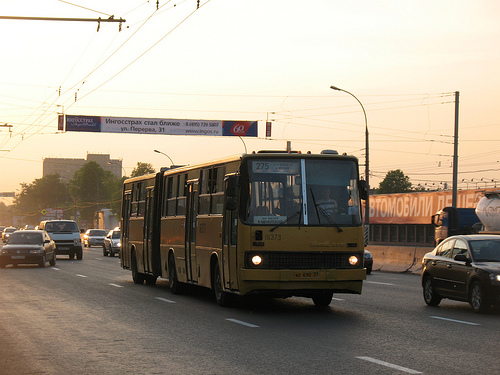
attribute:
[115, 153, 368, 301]
bus — yellow, large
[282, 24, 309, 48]
sky — twilight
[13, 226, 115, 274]
cars — small, black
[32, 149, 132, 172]
building — distant, large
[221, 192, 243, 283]
door — bus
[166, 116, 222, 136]
sign — unreadable, red, hanging, banner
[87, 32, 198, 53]
cables — electrical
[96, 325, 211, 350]
road — traffic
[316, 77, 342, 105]
light — black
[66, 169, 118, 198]
trees — distant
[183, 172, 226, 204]
window — large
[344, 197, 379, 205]
lettering — white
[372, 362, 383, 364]
lines — dotted